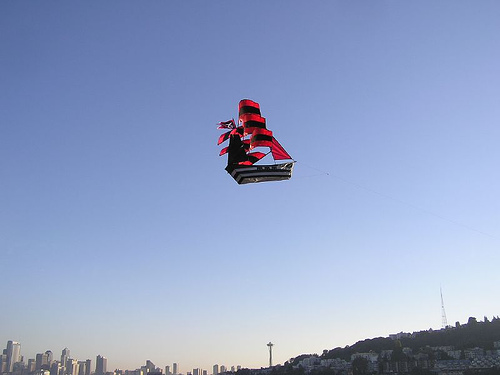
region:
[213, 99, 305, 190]
a white and black boat with red and black sails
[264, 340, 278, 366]
a street light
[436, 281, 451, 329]
a cell tower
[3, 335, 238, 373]
a city skyline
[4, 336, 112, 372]
tall buildings along skyline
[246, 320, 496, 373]
a hill with buildings on it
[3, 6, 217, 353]
a clear, blue sky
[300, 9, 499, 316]
a clear blue sky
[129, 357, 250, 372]
tall buildings along the skyline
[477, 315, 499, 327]
trees along the skyline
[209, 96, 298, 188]
a boat in the sky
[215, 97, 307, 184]
a red and black boat in the sky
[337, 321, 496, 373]
a hill of houses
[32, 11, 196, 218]
a clear blue sky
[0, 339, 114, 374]
a city in the distance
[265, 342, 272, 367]
a tall metal tower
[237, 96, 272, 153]
red and black sails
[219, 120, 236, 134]
red and black flag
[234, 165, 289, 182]
black and white bottom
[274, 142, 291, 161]
a red sail on front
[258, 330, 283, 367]
Tall ride in the back.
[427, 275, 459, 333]
Big skyscraper over building.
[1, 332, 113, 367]
Group of tall buildings to the left.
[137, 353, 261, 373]
Group of small buildings in the middle.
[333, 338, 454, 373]
Homes to the right.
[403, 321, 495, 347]
Bunch of bushes near the right.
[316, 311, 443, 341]
Bright horizon line over hill.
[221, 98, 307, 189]
Red and black kite in the sky.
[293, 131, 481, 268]
String in the sky for the kite.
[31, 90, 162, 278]
Clear blue skies above.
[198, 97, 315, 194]
a kite flying through the sky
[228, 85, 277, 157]
red and black sails of the kite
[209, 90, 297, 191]
a kite shaped like a boat in midair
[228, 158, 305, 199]
black and white boat base of the kite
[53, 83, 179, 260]
clear blue skies over the city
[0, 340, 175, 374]
a city skyline in the distance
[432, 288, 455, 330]
a radio tower on top of a hill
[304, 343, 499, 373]
many houses at the base of the hill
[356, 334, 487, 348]
trees growing on the hillside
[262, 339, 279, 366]
a needle shaped building in the distance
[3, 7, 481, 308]
The sky is clear blue.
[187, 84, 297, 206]
The kite is in the sky.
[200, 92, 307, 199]
The kite is a boat.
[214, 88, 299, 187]
The kite is red and black.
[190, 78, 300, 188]
The kite is large.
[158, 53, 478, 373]
The kite is flying above the buidings.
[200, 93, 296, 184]
The kite is flying.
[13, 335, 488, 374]
The city is below.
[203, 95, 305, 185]
The kite is a pirate ship.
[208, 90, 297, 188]
The boat is tan and black.